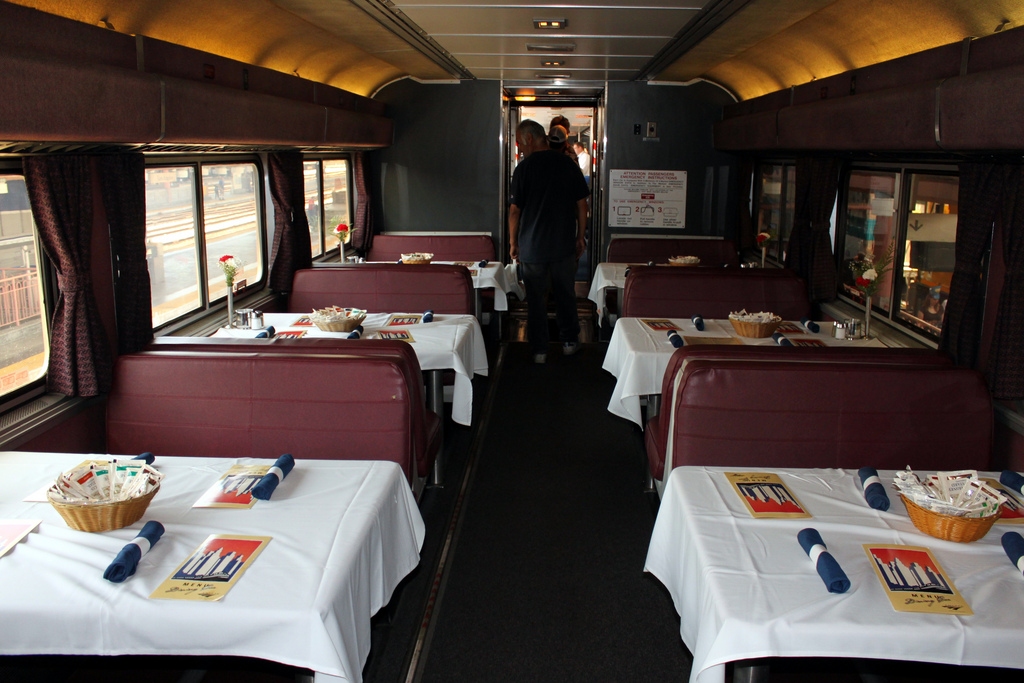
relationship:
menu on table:
[862, 534, 974, 623] [646, 456, 992, 679]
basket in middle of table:
[43, 450, 168, 533] [0, 444, 431, 673]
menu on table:
[146, 531, 279, 605] [0, 444, 431, 673]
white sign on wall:
[603, 163, 692, 231] [605, 67, 744, 249]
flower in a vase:
[217, 251, 243, 329] [220, 247, 251, 330]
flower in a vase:
[331, 219, 351, 264] [328, 217, 357, 263]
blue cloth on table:
[102, 520, 163, 583] [0, 428, 433, 664]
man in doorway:
[507, 113, 599, 363] [493, 91, 611, 310]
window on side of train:
[0, 173, 60, 418] [5, 4, 1021, 676]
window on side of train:
[138, 149, 272, 331] [5, 4, 1021, 676]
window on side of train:
[297, 148, 358, 263] [5, 4, 1021, 676]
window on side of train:
[839, 155, 966, 340] [5, 4, 1021, 676]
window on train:
[0, 173, 60, 418] [5, 4, 1021, 676]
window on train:
[138, 149, 272, 331] [5, 4, 1021, 676]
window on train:
[297, 148, 358, 263] [5, 4, 1021, 676]